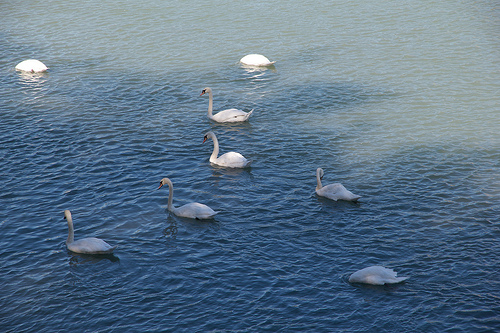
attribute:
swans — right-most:
[308, 159, 415, 289]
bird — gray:
[315, 165, 364, 204]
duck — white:
[208, 78, 268, 133]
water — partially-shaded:
[344, 39, 494, 157]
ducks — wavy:
[341, 258, 408, 289]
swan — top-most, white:
[237, 47, 278, 72]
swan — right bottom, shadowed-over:
[52, 205, 114, 260]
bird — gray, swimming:
[50, 206, 125, 262]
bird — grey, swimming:
[62, 208, 115, 253]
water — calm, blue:
[1, 6, 496, 330]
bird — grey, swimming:
[312, 165, 359, 201]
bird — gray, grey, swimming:
[155, 175, 218, 221]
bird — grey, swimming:
[200, 126, 252, 166]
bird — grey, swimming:
[197, 85, 254, 121]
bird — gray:
[348, 260, 413, 285]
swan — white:
[6, 51, 73, 105]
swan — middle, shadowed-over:
[305, 166, 366, 211]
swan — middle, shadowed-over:
[192, 75, 262, 130]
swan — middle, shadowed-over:
[197, 121, 259, 175]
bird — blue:
[58, 206, 116, 258]